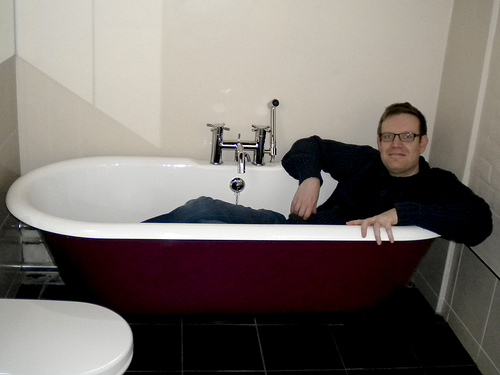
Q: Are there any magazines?
A: No, there are no magazines.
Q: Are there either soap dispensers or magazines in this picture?
A: No, there are no magazines or soap dispensers.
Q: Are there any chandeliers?
A: No, there are no chandeliers.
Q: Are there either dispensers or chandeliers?
A: No, there are no chandeliers or dispensers.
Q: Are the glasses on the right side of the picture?
A: Yes, the glasses are on the right of the image.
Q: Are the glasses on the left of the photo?
A: No, the glasses are on the right of the image.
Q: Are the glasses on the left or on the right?
A: The glasses are on the right of the image.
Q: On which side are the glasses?
A: The glasses are on the right of the image.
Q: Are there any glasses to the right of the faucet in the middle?
A: Yes, there are glasses to the right of the faucet.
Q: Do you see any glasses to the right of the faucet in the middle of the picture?
A: Yes, there are glasses to the right of the faucet.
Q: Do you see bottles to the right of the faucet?
A: No, there are glasses to the right of the faucet.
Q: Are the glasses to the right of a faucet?
A: Yes, the glasses are to the right of a faucet.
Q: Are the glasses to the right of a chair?
A: No, the glasses are to the right of a faucet.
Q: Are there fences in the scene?
A: No, there are no fences.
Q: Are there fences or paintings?
A: No, there are no fences or paintings.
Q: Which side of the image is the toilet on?
A: The toilet is on the left of the image.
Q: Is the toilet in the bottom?
A: Yes, the toilet is in the bottom of the image.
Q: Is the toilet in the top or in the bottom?
A: The toilet is in the bottom of the image.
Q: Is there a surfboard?
A: No, there are no surfboards.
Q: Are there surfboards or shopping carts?
A: No, there are no surfboards or shopping carts.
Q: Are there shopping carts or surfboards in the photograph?
A: No, there are no surfboards or shopping carts.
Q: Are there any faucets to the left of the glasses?
A: Yes, there is a faucet to the left of the glasses.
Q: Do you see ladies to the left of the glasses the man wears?
A: No, there is a faucet to the left of the glasses.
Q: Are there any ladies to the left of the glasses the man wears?
A: No, there is a faucet to the left of the glasses.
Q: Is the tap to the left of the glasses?
A: Yes, the tap is to the left of the glasses.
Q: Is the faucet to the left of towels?
A: No, the faucet is to the left of the glasses.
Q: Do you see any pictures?
A: No, there are no pictures.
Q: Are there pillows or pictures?
A: No, there are no pictures or pillows.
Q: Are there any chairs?
A: No, there are no chairs.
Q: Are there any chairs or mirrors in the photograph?
A: No, there are no chairs or mirrors.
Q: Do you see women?
A: No, there are no women.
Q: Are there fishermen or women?
A: No, there are no women or fishermen.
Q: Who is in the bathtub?
A: The man is in the bathtub.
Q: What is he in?
A: The man is in the bathtub.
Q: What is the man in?
A: The man is in the bathtub.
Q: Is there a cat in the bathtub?
A: No, there is a man in the bathtub.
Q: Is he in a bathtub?
A: Yes, the man is in a bathtub.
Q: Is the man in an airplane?
A: No, the man is in a bathtub.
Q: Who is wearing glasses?
A: The man is wearing glasses.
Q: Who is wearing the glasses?
A: The man is wearing glasses.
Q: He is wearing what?
A: The man is wearing glasses.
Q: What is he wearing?
A: The man is wearing glasses.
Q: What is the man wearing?
A: The man is wearing glasses.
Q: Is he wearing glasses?
A: Yes, the man is wearing glasses.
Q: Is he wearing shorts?
A: No, the man is wearing glasses.